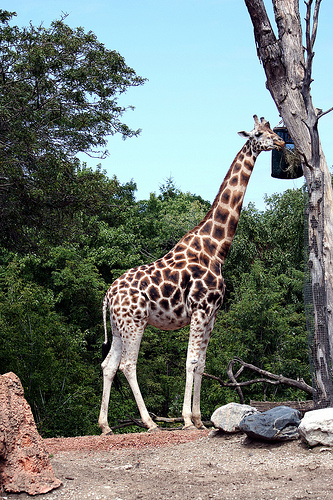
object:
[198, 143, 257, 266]
neck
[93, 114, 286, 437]
giraffe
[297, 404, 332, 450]
rock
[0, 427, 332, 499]
ground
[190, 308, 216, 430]
leg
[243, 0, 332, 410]
tree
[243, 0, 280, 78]
branch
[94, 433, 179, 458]
dirt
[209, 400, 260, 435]
stone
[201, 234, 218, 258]
spots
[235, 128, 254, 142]
ear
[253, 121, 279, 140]
hair